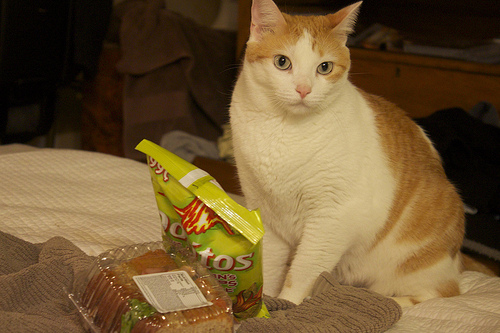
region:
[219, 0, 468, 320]
a white and brown cat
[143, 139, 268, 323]
a bag of chips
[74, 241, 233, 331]
a plastic box of tomatoes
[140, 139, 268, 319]
a green bag of Doritos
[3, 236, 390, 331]
a light brown towel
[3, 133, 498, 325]
a white bed spread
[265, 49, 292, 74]
a cat's right eye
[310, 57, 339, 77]
a cat's left eye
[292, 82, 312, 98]
a cat's pink nose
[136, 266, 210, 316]
a white product sticker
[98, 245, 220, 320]
sandwich in a plastic container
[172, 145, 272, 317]
bag of green doritos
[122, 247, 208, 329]
white sticker with black writing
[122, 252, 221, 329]
lettuce on a sandwich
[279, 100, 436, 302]
orange and white cat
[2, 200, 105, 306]
tan towel on bed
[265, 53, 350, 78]
two green cats eyes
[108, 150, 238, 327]
bag of doritos and sandwich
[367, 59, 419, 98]
key hole on a brown chest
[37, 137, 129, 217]
a white bed spread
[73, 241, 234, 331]
sandwich in plastic container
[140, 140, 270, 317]
yellow Doritos bag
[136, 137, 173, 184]
bag of Doritos costs 99 cents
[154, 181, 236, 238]
orange flame on yellow bag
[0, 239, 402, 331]
sandwich and chips on brown blanket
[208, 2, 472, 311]
cream and orange-colored cat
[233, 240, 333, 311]
cat's front paws on top blanket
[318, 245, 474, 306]
cat's hind legs and tail on bottom blanket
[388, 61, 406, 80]
small keyhole to open drawer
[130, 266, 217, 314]
nutrition information for sandwich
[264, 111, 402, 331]
a cat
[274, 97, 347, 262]
a cat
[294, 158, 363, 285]
a cat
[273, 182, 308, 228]
a cat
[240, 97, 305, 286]
a cat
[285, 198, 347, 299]
a cat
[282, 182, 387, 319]
a cat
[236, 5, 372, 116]
pink nose on cat face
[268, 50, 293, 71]
green eye of cat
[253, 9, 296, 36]
white hair in cat ear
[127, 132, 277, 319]
green bag of chips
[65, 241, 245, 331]
sand which in plastic box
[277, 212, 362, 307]
white leg of cat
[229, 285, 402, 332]
brown towel under cat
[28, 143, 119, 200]
white blanket under cat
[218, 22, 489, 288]
white and brown cat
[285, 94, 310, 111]
lips of a cat